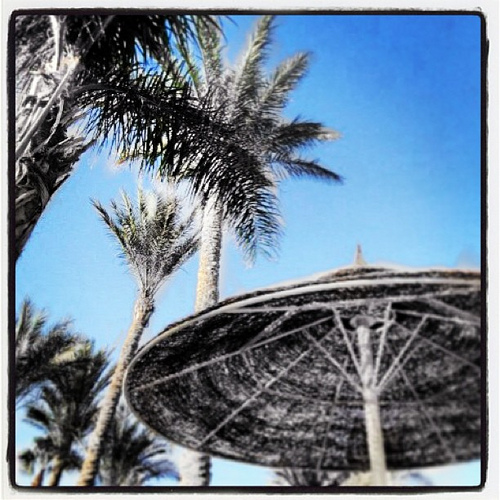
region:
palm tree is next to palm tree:
[111, 12, 345, 485]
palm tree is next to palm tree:
[74, 173, 229, 487]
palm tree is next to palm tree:
[12, 11, 235, 261]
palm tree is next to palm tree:
[10, 297, 81, 413]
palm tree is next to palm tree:
[18, 338, 119, 491]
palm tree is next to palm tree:
[85, 401, 181, 490]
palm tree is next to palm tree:
[273, 464, 352, 490]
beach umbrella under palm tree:
[121, 245, 482, 489]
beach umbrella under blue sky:
[119, 244, 483, 486]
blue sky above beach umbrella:
[10, 11, 477, 487]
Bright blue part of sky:
[378, 144, 456, 233]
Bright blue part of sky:
[390, 74, 444, 123]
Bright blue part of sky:
[401, 20, 464, 89]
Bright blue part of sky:
[420, 219, 477, 273]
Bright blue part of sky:
[317, 221, 396, 276]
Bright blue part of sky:
[234, 233, 325, 276]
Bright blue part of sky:
[271, 171, 336, 217]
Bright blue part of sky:
[304, 129, 371, 176]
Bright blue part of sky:
[301, 71, 358, 125]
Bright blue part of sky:
[282, 19, 353, 67]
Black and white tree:
[14, 295, 71, 402]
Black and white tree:
[28, 336, 95, 485]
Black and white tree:
[98, 180, 197, 322]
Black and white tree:
[155, 28, 317, 240]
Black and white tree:
[23, 14, 180, 196]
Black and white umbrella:
[118, 264, 470, 492]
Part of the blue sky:
[399, 209, 481, 259]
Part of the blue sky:
[385, 131, 441, 191]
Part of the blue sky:
[410, 172, 467, 213]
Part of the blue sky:
[26, 243, 118, 320]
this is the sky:
[343, 30, 395, 58]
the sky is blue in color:
[388, 34, 438, 91]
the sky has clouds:
[336, 199, 398, 246]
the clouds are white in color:
[307, 204, 366, 236]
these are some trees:
[7, 18, 322, 287]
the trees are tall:
[19, 17, 356, 273]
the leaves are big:
[148, 58, 279, 142]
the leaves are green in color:
[199, 40, 226, 81]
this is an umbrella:
[108, 233, 482, 490]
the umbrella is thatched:
[173, 352, 252, 407]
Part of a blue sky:
[410, 21, 441, 63]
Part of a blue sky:
[393, 159, 426, 193]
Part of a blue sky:
[335, 181, 383, 231]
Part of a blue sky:
[83, 295, 129, 348]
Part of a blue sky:
[31, 263, 63, 297]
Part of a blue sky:
[37, 195, 72, 237]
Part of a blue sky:
[65, 172, 126, 212]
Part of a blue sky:
[78, 133, 111, 190]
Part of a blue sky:
[145, 446, 204, 490]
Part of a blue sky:
[206, 447, 277, 489]